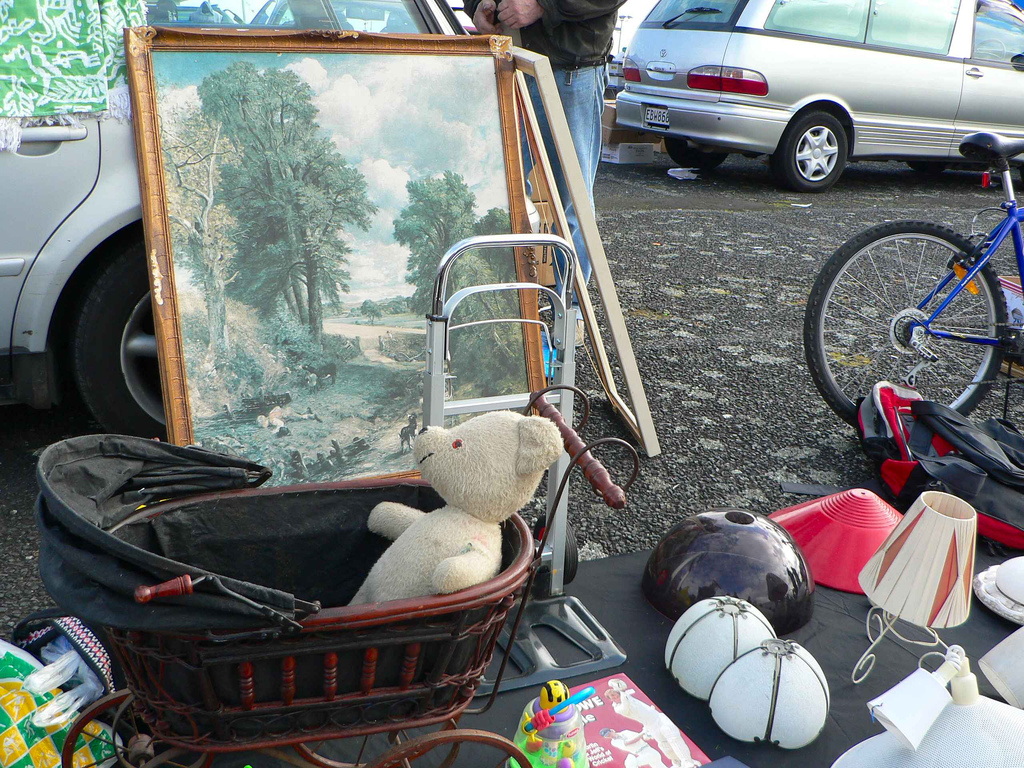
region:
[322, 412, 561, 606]
White teddy bear standing in a basket.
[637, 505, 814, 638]
Black dome like object sitting on the ground.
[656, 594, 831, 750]
Two white dome shaped objects sitting on the ground.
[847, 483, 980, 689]
White and pink lamp with legs in the shape of a scroll.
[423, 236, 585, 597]
White step ladder leaning against the basket.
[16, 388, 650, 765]
Black and red buggy carriage.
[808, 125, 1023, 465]
Blue bike parked beside red and black bag.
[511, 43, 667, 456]
White frame leaning against an object.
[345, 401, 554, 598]
white teddy bear in a carriage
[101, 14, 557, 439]
painting with gold frame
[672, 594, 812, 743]
white light fixtures on the table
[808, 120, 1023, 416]
blue bicycle with black seat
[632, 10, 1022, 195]
silver van behind the bicycle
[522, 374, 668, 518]
handle on the baby carriage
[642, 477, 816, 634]
black light fixture on the table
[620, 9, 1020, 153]
a silver van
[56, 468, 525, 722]
a brown and black basket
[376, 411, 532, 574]
a light brown teddy bear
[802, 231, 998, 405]
the bicycle tire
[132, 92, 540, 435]
a picture in a frame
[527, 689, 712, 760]
a book on the ground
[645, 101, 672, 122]
the license plate on the van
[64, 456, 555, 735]
red and black basket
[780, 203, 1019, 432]
black tire on bike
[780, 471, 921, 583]
red lampshade on driveway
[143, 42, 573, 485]
brown frame on picture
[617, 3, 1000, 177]
grey van is parked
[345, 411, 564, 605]
the stuffed animal is light brown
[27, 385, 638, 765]
the baby carriage is old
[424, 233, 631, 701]
the dolly is silver and gray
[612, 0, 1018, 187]
the van is silver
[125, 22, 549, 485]
the painting is large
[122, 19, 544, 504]
the painting is framed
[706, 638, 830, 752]
the glass lamp shade is white and silver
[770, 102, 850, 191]
the tire is black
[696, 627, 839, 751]
nick knack on the ground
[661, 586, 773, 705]
nick knack on the ground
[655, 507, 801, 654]
nick knack on the ground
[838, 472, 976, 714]
nick knack on the ground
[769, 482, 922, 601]
nick knack on the ground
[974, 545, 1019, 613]
nick knack on the ground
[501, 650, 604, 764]
nick knack on the ground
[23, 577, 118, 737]
nick knack on the ground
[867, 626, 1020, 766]
nick knack on the ground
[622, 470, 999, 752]
Lamp shades sitting on the ground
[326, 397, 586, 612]
A teddybear in a basket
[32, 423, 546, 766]
The basket holding a teddy bear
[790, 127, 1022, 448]
A blue bicycle sitting on the ground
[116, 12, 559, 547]
A painting in a gold rim